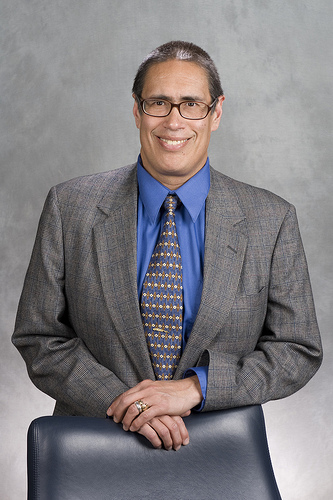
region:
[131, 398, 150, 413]
Two metal rings on the man's finger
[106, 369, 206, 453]
Man's white hands clasped together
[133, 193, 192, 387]
Dark blue patterned tie around the man's neck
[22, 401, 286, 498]
Top of a dark blue chair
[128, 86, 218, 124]
Pair of brown-rimmed glasses on the man's face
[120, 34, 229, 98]
Dark brown short hair on the man's head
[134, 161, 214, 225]
Blue collar of the man's buttoned shirt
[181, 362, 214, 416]
Blue sleeve of the man's shirt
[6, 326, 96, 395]
Wrinkles in the arm of the man's jacket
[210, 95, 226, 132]
Man's large left ear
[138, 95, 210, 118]
The eyeglasses the man is wearing.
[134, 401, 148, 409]
The rings on the man's finger.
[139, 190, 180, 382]
The tie the man is wearing.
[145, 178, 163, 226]
The left collar of the man's shirt.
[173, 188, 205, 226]
The right collar of the man's shirt.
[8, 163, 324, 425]
The gray blazer the man is wearing.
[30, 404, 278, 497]
The leather chair the man has his hands on.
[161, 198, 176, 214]
The knot of the tie.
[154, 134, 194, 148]
The mouth of the man.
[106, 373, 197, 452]
The hands of the man.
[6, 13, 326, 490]
A smiling man in a suit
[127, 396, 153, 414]
A man's gold ring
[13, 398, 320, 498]
A blue leather chair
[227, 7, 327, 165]
A gray wall surface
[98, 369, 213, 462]
A man's two hands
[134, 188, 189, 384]
A man's blue and gold tie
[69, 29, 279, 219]
A smiling man wearing eyeglasses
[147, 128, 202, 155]
A man's lips and teeth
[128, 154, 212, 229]
A man's blue shirt collar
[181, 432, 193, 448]
A man's fingernail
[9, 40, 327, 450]
a man wearing a grey suit and a tie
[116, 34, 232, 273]
a man wearing a blue shirt with a tie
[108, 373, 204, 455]
the crossed hands of a man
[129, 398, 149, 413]
rings on a finger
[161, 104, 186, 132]
the nose of a man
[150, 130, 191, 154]
the mouth of a man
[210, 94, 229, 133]
the ear of a man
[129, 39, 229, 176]
a man wearing glasses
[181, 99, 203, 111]
the eye of a man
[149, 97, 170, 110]
the eye of a man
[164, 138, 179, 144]
teeth of the man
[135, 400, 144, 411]
rings on the man's finger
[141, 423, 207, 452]
the man's fingers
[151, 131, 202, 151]
the mouth of the man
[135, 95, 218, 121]
the man's spectacles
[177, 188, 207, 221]
the collar of the man's blue shirt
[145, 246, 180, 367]
a tie on the man's neck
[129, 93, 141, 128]
the ear of the man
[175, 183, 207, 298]
a blue shirt of the man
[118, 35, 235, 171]
the head of a man